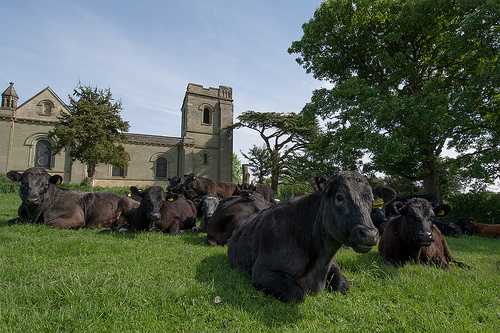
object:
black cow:
[228, 170, 380, 304]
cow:
[206, 191, 274, 247]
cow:
[378, 197, 471, 272]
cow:
[5, 167, 140, 229]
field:
[0, 193, 500, 333]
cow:
[457, 217, 477, 236]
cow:
[119, 186, 198, 237]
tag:
[373, 195, 384, 208]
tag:
[437, 208, 444, 215]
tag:
[168, 197, 174, 202]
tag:
[56, 178, 61, 185]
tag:
[127, 190, 132, 197]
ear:
[308, 171, 329, 191]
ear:
[372, 186, 396, 202]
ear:
[433, 203, 452, 217]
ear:
[391, 200, 404, 215]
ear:
[50, 174, 64, 184]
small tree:
[44, 74, 131, 188]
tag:
[167, 197, 173, 202]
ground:
[416, 183, 444, 225]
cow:
[182, 173, 240, 199]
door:
[34, 140, 51, 168]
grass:
[0, 190, 500, 331]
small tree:
[217, 106, 321, 195]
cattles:
[6, 168, 500, 302]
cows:
[0, 168, 500, 303]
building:
[0, 82, 234, 187]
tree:
[215, 0, 499, 223]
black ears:
[309, 172, 327, 189]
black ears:
[377, 186, 396, 200]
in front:
[227, 172, 379, 304]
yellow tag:
[373, 198, 384, 209]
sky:
[0, 0, 500, 195]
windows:
[0, 82, 234, 187]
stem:
[217, 122, 261, 136]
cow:
[228, 171, 379, 303]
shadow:
[150, 130, 232, 183]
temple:
[0, 82, 18, 108]